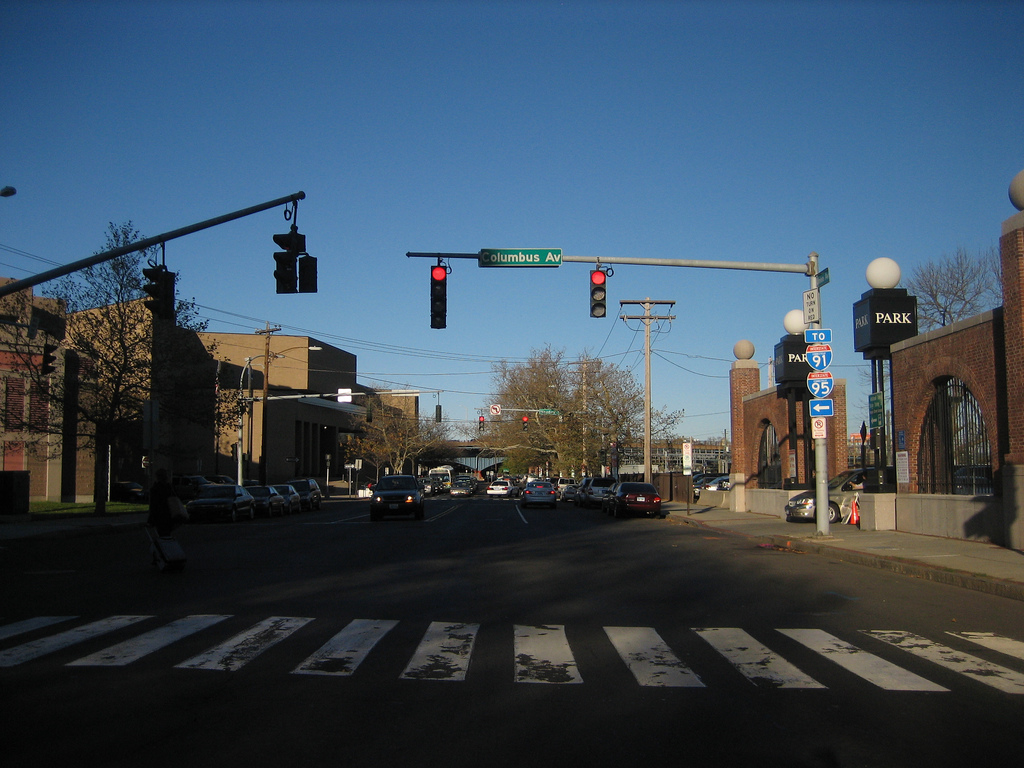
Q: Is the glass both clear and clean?
A: Yes, the glass is clear and clean.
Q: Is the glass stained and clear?
A: No, the glass is clear but clean.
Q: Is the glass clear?
A: Yes, the glass is clear.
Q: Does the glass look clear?
A: Yes, the glass is clear.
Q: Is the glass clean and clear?
A: Yes, the glass is clean and clear.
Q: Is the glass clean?
A: Yes, the glass is clean.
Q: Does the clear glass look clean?
A: Yes, the glass is clean.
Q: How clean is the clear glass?
A: The glass is clean.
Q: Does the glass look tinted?
A: No, the glass is clean.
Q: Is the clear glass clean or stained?
A: The glass is clean.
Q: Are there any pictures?
A: No, there are no pictures.